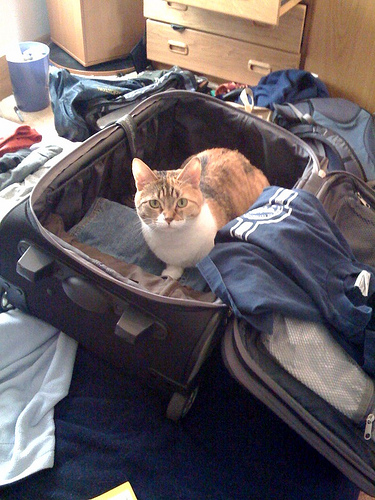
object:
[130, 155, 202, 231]
head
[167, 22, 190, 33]
clothes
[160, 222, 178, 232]
mouth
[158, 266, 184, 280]
paw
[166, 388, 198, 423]
suitcase wheels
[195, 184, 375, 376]
shirt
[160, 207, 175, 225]
nose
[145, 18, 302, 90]
drawer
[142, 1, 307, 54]
drawer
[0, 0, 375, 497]
bureau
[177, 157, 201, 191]
ear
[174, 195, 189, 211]
eye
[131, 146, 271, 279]
cat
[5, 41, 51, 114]
trashcan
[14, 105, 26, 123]
pen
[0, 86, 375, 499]
suitcase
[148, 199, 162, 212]
eye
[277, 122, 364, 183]
strap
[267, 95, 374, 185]
bag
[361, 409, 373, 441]
zipper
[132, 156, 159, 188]
ears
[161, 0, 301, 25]
open drawer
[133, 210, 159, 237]
whiskers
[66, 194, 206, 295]
jeans